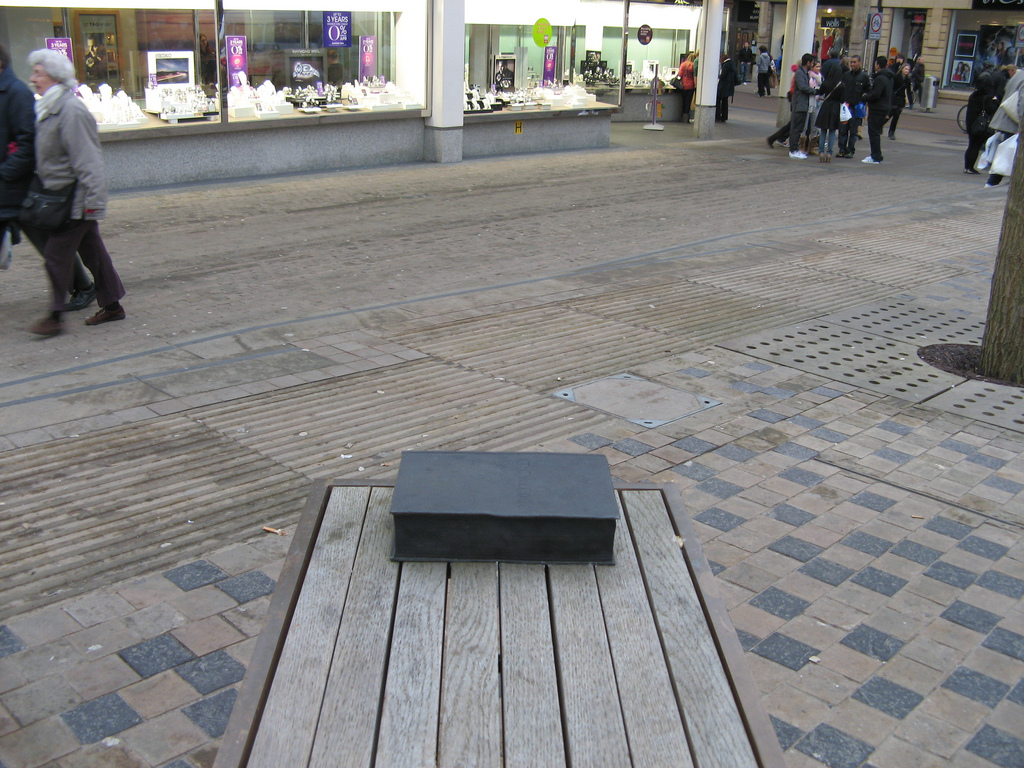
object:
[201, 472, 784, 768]
table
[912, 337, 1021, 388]
planter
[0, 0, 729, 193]
store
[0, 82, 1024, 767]
sidewalk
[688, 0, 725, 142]
pillars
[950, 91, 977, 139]
bike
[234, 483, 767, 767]
plank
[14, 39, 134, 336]
lady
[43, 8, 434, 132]
window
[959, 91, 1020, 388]
tree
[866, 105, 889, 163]
jeans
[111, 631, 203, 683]
stone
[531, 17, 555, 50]
sign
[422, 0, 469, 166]
pillar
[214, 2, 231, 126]
divider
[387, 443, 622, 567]
box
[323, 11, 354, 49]
poster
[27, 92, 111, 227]
gray coat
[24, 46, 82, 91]
white hair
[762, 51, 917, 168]
people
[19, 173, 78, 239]
black purse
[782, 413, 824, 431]
bricks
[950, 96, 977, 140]
wheel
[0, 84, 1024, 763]
ground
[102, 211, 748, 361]
pathway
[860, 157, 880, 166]
shoe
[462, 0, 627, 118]
window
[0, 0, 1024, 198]
wall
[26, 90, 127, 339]
body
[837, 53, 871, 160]
person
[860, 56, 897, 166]
person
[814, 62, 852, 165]
person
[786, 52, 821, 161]
person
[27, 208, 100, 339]
leg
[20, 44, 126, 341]
woman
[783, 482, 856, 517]
brick